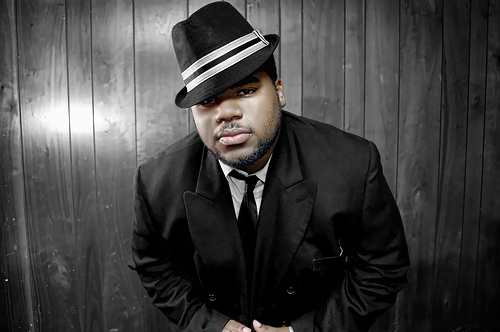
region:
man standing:
[77, 6, 422, 329]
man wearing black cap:
[169, 0, 286, 108]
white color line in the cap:
[147, 29, 274, 92]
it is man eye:
[183, 82, 272, 107]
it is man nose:
[212, 97, 248, 124]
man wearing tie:
[233, 171, 260, 301]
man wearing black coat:
[122, 109, 414, 330]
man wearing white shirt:
[217, 159, 275, 230]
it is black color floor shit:
[23, 37, 113, 279]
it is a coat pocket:
[299, 241, 355, 291]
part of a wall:
[450, 205, 477, 230]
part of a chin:
[237, 154, 248, 160]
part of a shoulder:
[341, 145, 357, 159]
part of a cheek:
[251, 127, 261, 140]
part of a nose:
[228, 132, 230, 152]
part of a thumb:
[269, 322, 282, 328]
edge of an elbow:
[370, 283, 405, 290]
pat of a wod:
[384, 149, 431, 231]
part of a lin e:
[418, 105, 463, 158]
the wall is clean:
[23, 57, 114, 124]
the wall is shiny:
[36, 89, 110, 136]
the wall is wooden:
[51, 184, 113, 301]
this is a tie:
[236, 177, 261, 232]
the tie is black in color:
[242, 197, 256, 224]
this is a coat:
[315, 163, 367, 231]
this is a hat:
[169, 2, 284, 108]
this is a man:
[130, 14, 410, 319]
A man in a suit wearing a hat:
[117, 3, 412, 330]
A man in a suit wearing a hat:
[125, 5, 415, 328]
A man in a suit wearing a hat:
[117, 5, 417, 325]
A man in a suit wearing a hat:
[113, 2, 413, 328]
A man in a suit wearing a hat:
[113, 7, 410, 327]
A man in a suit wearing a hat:
[120, 5, 415, 321]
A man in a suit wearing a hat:
[121, 2, 421, 322]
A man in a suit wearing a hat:
[117, 11, 419, 329]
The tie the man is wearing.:
[228, 167, 260, 261]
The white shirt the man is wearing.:
[213, 154, 272, 218]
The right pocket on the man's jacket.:
[310, 253, 343, 269]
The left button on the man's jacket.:
[206, 290, 216, 300]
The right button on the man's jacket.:
[287, 286, 294, 293]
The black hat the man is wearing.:
[160, 1, 285, 106]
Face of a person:
[170, 47, 288, 182]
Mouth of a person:
[208, 122, 258, 151]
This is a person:
[135, 10, 371, 325]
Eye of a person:
[230, 80, 261, 98]